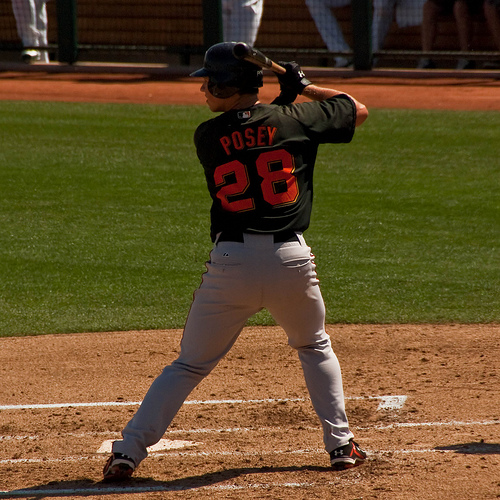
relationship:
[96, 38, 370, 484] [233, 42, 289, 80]
baseball player holding baseball bat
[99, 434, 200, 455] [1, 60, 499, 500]
baseball plate sitting on ground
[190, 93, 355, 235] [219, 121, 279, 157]
baseball jersey says posey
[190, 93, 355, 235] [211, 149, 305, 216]
baseball jersey has number 28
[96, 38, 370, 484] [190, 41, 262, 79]
baseball player has baseball helmet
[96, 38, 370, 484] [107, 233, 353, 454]
baseball player has baseball pants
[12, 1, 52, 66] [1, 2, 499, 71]
player watching from dugout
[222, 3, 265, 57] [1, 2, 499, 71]
player watching from dugout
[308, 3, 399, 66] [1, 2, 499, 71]
player watching from dugout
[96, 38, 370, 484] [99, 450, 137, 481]
baseball player has sneaker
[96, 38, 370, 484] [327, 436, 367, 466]
baseball player has sneaker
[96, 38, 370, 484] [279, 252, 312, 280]
baseball player has hind pocket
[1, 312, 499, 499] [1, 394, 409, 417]
patch of dirt has white line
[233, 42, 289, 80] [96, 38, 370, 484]
baseball bat behind held by baseball player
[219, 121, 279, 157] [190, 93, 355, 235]
posey written on baseball jersey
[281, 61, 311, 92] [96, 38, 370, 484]
glove worn by baseball player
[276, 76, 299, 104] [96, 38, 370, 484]
glove worn by baseball player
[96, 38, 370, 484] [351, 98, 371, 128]
baseball player has elbow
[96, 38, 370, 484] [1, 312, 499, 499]
baseball player standing in patch of dirt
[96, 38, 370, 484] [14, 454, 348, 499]
baseball player has shadow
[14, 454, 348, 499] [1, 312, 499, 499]
shadow across patch of dirt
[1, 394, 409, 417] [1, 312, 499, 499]
white line on top of patch of dirt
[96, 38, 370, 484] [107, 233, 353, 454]
baseball player wearing baseball pants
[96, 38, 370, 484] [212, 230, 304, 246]
baseball player has belt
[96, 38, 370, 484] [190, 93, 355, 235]
baseball player has baseball jersey